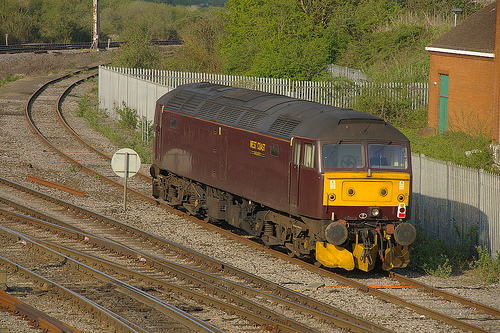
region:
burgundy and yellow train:
[134, 62, 431, 287]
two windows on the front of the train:
[307, 132, 415, 174]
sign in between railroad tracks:
[107, 142, 146, 222]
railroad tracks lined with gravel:
[8, 189, 234, 331]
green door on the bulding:
[426, 66, 458, 152]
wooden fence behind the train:
[87, 50, 212, 131]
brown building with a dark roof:
[403, 24, 496, 161]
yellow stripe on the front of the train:
[292, 160, 422, 220]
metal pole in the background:
[72, 2, 117, 72]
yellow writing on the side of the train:
[232, 127, 284, 170]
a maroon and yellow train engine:
[147, 71, 420, 278]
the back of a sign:
[107, 141, 144, 218]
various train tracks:
[2, 276, 494, 329]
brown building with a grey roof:
[422, 3, 498, 138]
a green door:
[430, 66, 452, 136]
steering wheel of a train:
[337, 151, 358, 173]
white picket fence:
[292, 81, 426, 113]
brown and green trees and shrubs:
[113, 2, 424, 76]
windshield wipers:
[322, 134, 402, 158]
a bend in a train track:
[5, 49, 98, 182]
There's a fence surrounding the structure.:
[83, 62, 498, 261]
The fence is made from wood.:
[91, 57, 498, 262]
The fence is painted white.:
[68, 50, 498, 287]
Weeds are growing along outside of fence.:
[77, 96, 494, 294]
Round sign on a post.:
[109, 140, 145, 220]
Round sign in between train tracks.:
[111, 147, 142, 223]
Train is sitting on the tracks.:
[129, 72, 424, 286]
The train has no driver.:
[318, 144, 365, 181]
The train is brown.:
[145, 83, 428, 278]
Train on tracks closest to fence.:
[136, 67, 444, 279]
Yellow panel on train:
[309, 168, 423, 203]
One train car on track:
[115, 70, 456, 283]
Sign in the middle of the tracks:
[82, 140, 154, 203]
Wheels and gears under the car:
[149, 169, 309, 249]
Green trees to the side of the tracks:
[212, 1, 424, 68]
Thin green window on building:
[433, 68, 454, 138]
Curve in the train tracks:
[13, 63, 95, 158]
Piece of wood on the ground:
[5, 165, 94, 201]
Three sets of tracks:
[0, 182, 240, 332]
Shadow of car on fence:
[422, 190, 491, 259]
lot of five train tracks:
[16, 70, 170, 320]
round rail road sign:
[78, 149, 152, 224]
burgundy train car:
[113, 109, 388, 204]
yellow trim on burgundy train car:
[318, 174, 419, 287]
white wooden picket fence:
[82, 71, 402, 126]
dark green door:
[418, 66, 491, 153]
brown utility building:
[422, 59, 494, 144]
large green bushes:
[149, 13, 429, 73]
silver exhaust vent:
[436, 11, 469, 38]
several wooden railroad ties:
[70, 205, 209, 269]